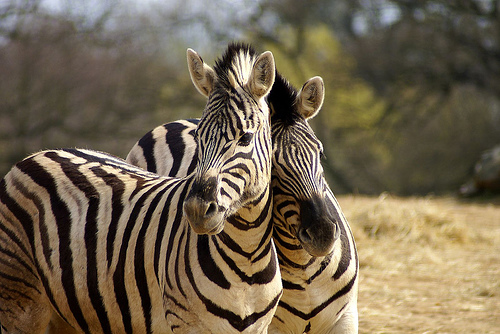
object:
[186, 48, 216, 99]
ear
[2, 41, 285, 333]
zebra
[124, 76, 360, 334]
zebra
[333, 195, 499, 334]
field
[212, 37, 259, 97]
mane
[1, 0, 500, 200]
trees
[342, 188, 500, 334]
grass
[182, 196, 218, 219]
nose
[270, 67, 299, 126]
black mane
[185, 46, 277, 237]
head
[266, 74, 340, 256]
head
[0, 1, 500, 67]
sky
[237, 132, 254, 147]
eye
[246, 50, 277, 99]
ear